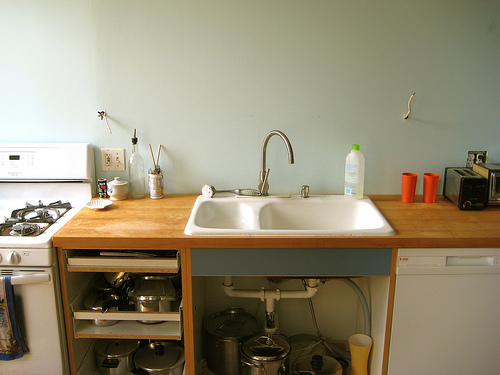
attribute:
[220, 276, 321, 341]
pipe — white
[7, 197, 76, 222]
burner — black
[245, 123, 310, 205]
faucet — large, silver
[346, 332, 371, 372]
cup — bright, yellow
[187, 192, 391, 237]
kitchen sink — large, white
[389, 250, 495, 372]
dishwasher — white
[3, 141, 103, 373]
oven — white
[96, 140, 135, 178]
outlet — electrical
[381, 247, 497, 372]
dishwasher — white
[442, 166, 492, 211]
toaster — black, silver, two slice, metal, gray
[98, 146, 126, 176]
wall outlet — white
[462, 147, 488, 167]
wall outlet — white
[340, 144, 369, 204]
bottle — clear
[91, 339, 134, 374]
pot — metal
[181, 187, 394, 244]
sink — white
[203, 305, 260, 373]
pot — large, gray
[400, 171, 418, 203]
cup — orange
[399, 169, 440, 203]
cups —  orange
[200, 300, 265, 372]
pots — silver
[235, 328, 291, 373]
pots — silver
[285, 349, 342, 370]
pots — silver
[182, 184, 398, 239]
sink — white, porcelain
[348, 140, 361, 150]
cap — green